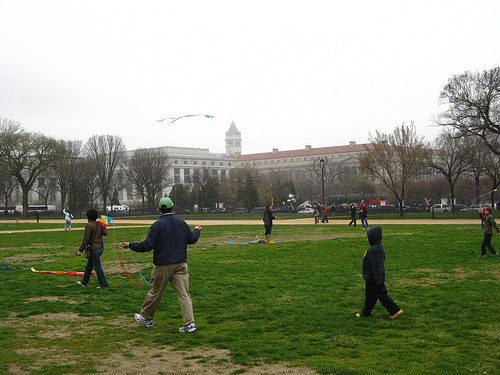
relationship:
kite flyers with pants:
[119, 197, 202, 334] [138, 262, 198, 323]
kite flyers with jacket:
[119, 197, 202, 334] [129, 214, 201, 264]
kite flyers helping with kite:
[119, 197, 202, 334] [155, 109, 217, 131]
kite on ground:
[153, 109, 217, 124] [1, 213, 499, 373]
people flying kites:
[30, 139, 495, 344] [150, 110, 214, 123]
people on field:
[30, 139, 495, 344] [6, 214, 495, 374]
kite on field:
[219, 238, 275, 247] [6, 214, 495, 374]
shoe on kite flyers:
[156, 326, 206, 348] [119, 197, 202, 334]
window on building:
[171, 164, 182, 186] [0, 121, 497, 209]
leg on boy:
[473, 239, 493, 256] [474, 204, 498, 257]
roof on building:
[234, 143, 499, 162] [238, 142, 499, 207]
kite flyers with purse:
[76, 209, 111, 290] [82, 235, 94, 260]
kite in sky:
[155, 114, 214, 125] [4, 2, 496, 159]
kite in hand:
[99, 213, 119, 227] [99, 212, 107, 222]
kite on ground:
[29, 267, 96, 276] [1, 213, 499, 373]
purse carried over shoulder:
[78, 244, 97, 262] [75, 220, 97, 236]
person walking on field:
[113, 189, 210, 335] [6, 214, 495, 374]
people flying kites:
[64, 196, 499, 334] [160, 108, 254, 126]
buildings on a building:
[225, 119, 243, 156] [0, 121, 497, 209]